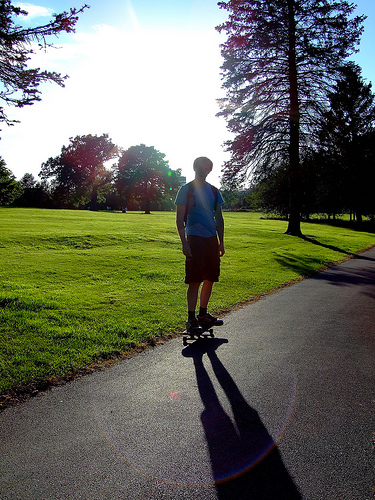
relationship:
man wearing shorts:
[172, 153, 231, 335] [175, 233, 221, 286]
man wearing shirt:
[172, 153, 231, 335] [171, 180, 226, 240]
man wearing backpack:
[172, 153, 231, 335] [180, 185, 220, 219]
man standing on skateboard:
[172, 153, 231, 335] [175, 306, 218, 343]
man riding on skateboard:
[172, 153, 231, 335] [175, 306, 218, 343]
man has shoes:
[172, 153, 231, 335] [184, 309, 226, 333]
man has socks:
[172, 153, 231, 335] [177, 306, 212, 318]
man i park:
[172, 153, 231, 335] [8, 5, 374, 497]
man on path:
[172, 153, 231, 335] [6, 241, 374, 499]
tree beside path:
[216, 2, 364, 238] [6, 241, 374, 499]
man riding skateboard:
[172, 153, 231, 335] [175, 306, 218, 343]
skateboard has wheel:
[175, 306, 218, 343] [183, 336, 191, 346]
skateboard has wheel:
[175, 306, 218, 343] [207, 323, 220, 337]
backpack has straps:
[180, 185, 220, 219] [183, 185, 193, 214]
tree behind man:
[216, 2, 364, 238] [172, 153, 231, 335]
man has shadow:
[172, 153, 231, 335] [185, 338, 303, 499]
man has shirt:
[172, 153, 231, 335] [171, 180, 226, 240]